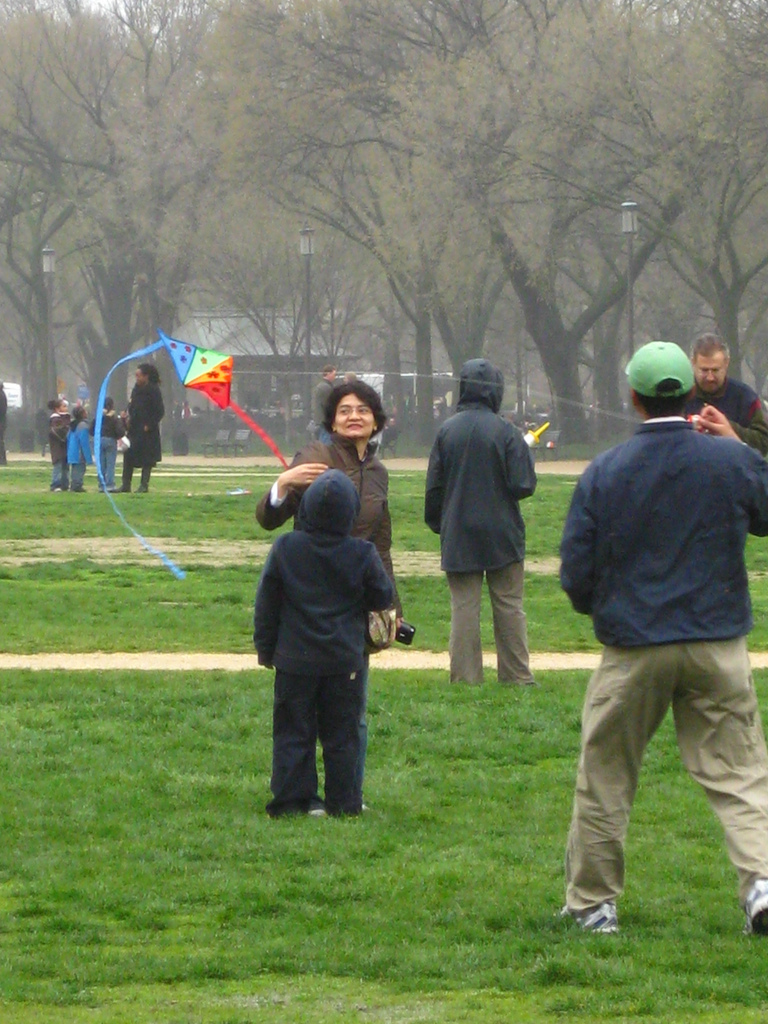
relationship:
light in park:
[271, 184, 379, 415] [271, 60, 737, 415]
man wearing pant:
[504, 351, 750, 883] [504, 633, 750, 883]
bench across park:
[167, 404, 284, 469] [167, 31, 678, 807]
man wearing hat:
[589, 359, 764, 615] [589, 359, 764, 400]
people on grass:
[75, 361, 719, 818] [75, 361, 719, 818]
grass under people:
[85, 709, 431, 926] [85, 368, 431, 926]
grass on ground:
[0, 667, 768, 1023] [57, 706, 398, 930]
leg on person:
[508, 697, 664, 942] [508, 352, 735, 942]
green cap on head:
[625, 341, 696, 398] [594, 339, 758, 466]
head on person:
[594, 339, 758, 466] [551, 339, 758, 818]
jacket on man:
[561, 328, 757, 575] [561, 328, 757, 575]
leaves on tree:
[278, 4, 761, 179] [206, 1, 599, 455]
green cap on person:
[618, 327, 696, 407] [549, 333, 767, 937]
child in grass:
[223, 457, 431, 927] [223, 814, 431, 927]